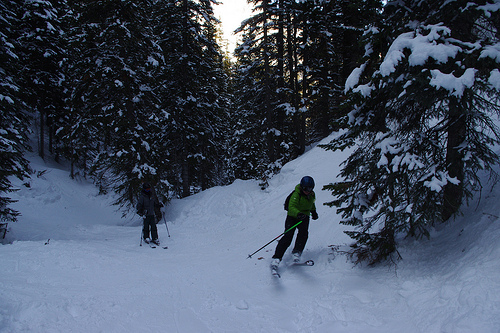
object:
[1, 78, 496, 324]
mountain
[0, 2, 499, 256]
forest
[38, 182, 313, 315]
snow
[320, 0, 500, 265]
trees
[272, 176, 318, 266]
skiers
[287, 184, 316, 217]
jacket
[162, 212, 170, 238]
ski pole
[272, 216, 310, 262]
pants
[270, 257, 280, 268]
shoes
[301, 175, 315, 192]
helmet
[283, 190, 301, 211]
backpack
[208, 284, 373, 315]
tracks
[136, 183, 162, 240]
person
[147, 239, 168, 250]
skis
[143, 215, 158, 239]
pants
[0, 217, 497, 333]
ground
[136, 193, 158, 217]
black outfit